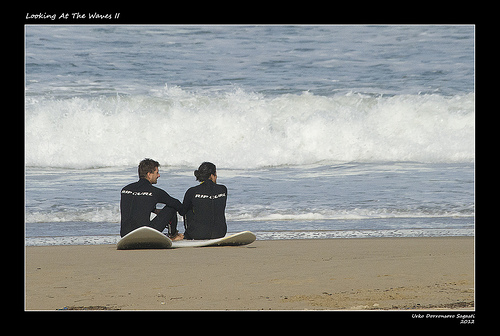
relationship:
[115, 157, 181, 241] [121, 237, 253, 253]
man on surfboards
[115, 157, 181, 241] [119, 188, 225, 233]
man wear wetsuits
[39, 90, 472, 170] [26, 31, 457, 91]
wave on water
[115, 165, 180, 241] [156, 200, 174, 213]
man has knees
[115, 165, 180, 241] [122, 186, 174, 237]
man wears wetsuit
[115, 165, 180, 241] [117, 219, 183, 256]
man sits on surfboard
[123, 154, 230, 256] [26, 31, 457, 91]
couple looks at water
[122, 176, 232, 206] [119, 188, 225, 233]
letters on wetsuits